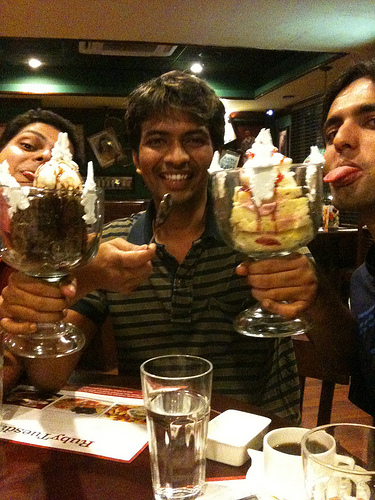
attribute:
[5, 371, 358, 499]
table — brown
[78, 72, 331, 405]
man — smiling, holding, smelling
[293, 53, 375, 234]
person — licking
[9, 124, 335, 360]
ice cream — held, clear, vanilla, cold, brown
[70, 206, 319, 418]
shirt — striped, green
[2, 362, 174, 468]
mat — paper, white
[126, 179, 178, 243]
spoon — small, silver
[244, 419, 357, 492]
mug — small, full, white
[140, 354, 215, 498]
glass — tall, full